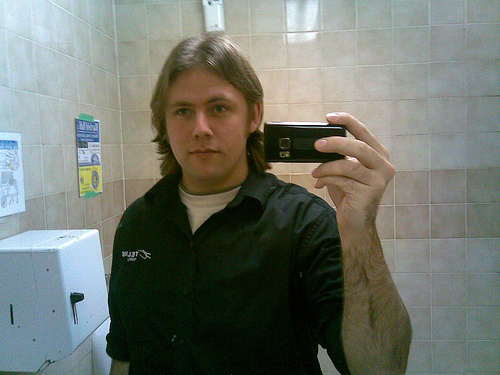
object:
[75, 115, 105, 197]
paper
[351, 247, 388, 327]
hair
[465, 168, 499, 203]
tile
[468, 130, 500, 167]
tile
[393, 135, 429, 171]
tile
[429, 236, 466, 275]
tile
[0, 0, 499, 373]
mirror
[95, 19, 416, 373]
person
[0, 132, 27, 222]
paper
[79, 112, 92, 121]
tape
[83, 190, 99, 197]
tape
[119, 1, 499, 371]
wall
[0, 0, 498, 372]
bathroom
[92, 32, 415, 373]
man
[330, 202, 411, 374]
arm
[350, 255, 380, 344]
hair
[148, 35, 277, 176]
hair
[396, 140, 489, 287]
stripe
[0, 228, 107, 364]
dispenser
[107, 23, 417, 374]
man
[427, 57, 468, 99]
tile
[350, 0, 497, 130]
tile wall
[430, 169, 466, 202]
tile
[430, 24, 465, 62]
tile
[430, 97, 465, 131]
tile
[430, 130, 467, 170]
tile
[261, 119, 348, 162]
cell phone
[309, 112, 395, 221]
hand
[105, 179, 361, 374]
shirt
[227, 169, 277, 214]
collar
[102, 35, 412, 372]
person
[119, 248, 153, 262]
writing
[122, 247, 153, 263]
logo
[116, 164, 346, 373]
black shirt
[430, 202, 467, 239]
tile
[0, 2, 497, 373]
wall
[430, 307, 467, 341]
tile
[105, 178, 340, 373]
tshirt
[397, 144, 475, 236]
tiles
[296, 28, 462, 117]
walls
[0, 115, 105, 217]
papers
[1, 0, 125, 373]
wall